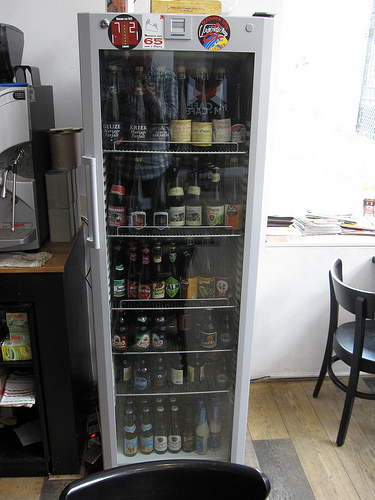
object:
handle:
[81, 153, 101, 248]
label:
[153, 433, 166, 450]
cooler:
[74, 11, 277, 480]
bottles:
[122, 406, 138, 454]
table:
[1, 220, 94, 477]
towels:
[0, 372, 39, 405]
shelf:
[264, 204, 375, 247]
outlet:
[85, 402, 104, 442]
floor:
[245, 373, 374, 500]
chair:
[313, 257, 375, 447]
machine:
[0, 22, 83, 251]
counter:
[1, 248, 77, 273]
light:
[86, 423, 97, 440]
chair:
[62, 455, 278, 499]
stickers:
[197, 12, 233, 48]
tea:
[2, 337, 33, 359]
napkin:
[13, 417, 42, 447]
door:
[77, 10, 275, 463]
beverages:
[193, 66, 213, 147]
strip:
[82, 440, 104, 465]